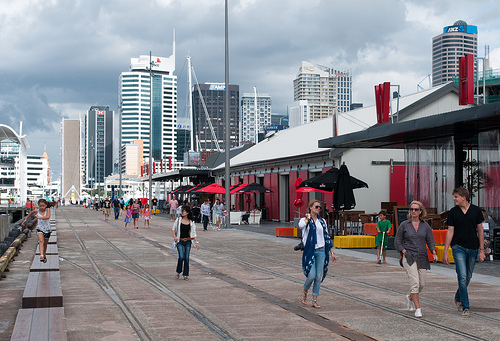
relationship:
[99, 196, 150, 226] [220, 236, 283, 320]
pedestrians on a walkway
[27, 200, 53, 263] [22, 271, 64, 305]
girl running on bench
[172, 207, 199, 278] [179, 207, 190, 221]
woman walking and looking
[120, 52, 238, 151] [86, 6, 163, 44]
skyscrapers near clouds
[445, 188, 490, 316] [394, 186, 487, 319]
man and woman walking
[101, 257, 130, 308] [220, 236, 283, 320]
metal tracks on walkway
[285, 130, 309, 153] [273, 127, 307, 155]
white building with curved roof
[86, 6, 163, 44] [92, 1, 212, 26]
clouds in sky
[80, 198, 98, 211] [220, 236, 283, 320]
people on walkway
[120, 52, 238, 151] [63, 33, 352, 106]
skyscrapers in background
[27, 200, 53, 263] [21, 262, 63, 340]
girl running on benches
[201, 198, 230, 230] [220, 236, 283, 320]
couple walking down walkway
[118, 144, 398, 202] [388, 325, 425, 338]
businesses on side of street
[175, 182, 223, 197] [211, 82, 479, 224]
umbrellas in front of building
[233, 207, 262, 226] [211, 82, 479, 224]
tables in front of building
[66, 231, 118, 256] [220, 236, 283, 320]
tracks on walkway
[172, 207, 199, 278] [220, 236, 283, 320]
woman walking down walkway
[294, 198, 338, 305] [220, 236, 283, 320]
girl walking on walkway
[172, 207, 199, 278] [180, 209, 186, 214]
woman wearing sunglasses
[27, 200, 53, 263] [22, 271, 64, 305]
girl running on a bench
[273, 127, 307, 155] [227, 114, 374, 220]
roof on a building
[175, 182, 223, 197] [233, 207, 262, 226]
umbrellas over tables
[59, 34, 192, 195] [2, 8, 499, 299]
buildings in a city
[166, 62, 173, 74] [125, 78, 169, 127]
white building with glass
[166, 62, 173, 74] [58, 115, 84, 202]
white and brown building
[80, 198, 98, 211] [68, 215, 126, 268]
people walking on a boardwalk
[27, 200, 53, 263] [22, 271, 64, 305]
girl hopping on bench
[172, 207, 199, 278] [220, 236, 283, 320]
woman walking on walkway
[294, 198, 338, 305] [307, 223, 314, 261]
woman wearing a scarf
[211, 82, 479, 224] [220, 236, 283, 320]
building near walkway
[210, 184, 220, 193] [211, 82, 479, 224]
red umbrella by building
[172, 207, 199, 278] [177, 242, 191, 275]
woman wearing jeans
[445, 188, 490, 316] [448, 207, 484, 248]
man with black shirt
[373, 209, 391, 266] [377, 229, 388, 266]
boy with scooter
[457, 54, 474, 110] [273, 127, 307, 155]
red on roof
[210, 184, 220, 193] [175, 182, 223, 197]
red and black umbrellas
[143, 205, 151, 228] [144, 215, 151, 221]
girl with white shorts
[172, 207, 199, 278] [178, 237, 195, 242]
woman wearing brown belt